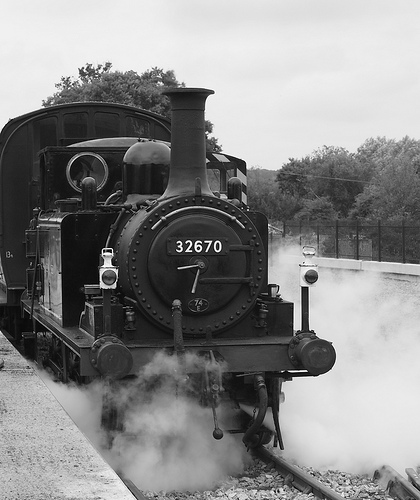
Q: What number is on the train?
A: 32670.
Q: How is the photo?
A: Clear.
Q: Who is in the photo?
A: Nobody.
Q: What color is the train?
A: Black.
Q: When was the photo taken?
A: Daytime.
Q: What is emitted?
A: Smoke.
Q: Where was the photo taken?
A: At a train station.